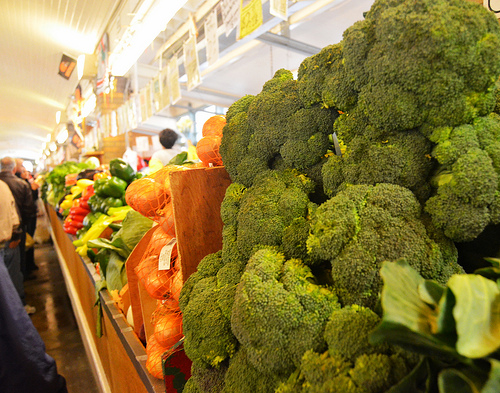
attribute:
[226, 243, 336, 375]
broccoli — piled, green, floret, large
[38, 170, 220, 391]
stand — full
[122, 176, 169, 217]
onion — netted, brown, bagged, orange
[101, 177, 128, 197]
pepper — green, bell, piled, red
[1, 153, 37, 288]
man — lined up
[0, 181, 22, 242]
coat — tan, beige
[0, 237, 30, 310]
jeans — blue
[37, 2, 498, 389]
produce — sale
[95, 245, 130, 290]
cabbage — leafy, green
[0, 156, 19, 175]
head — bald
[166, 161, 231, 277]
wood — frame, brown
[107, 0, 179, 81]
light — bright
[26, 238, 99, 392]
floor — shiny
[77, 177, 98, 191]
zucchini — yellow